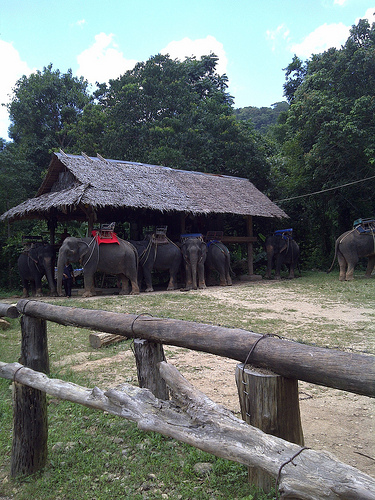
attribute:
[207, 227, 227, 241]
bench — brown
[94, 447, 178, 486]
rocks — small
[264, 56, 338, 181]
bushes — green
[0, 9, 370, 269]
tall trees — multiple, green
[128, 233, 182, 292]
elephant — standing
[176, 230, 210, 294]
elephant — standing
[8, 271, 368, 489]
grass — green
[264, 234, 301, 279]
elephant — dark, gray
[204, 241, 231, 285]
elephant — dark, gray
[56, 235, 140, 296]
elephant — dark, gray, grey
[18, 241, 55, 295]
elephant — dark, gray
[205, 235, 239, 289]
elephant — standing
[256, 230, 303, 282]
elephant — standing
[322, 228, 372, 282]
elephant — dark, gray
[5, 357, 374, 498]
log — tree log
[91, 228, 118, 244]
blanket — red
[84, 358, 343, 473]
log — weathered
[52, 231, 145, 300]
elephant — standing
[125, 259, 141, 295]
leg — elephant's leg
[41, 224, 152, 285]
elephant — light, gray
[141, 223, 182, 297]
elephant seat — brown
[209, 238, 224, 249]
blanket — blue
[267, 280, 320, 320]
sand — patch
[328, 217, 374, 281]
elephant — grey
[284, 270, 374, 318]
grass — patch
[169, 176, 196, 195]
hay — dead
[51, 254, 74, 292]
trunk — elephant's trunk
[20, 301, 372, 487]
fence — wooden, wooden pole fence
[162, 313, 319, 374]
pole — wooden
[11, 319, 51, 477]
stump — tree stump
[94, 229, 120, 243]
seat — red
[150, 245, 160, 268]
straps — beneath